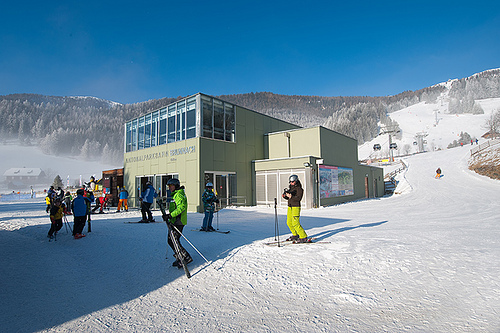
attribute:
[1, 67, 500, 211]
mountain — snowy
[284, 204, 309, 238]
ski pants — yellow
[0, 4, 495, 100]
skies — blue, crystal clear, clear, bright blue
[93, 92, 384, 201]
ski lodge — tan, modern, large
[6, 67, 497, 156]
trees — green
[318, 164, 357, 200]
map — large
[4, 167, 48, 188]
building — small, brown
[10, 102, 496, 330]
snow — white, light layer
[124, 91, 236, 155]
windows — glass, tall, large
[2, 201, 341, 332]
large shadow — large 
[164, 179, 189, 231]
jacket — green, bright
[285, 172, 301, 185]
helmet — silver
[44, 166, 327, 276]
skiing — sport